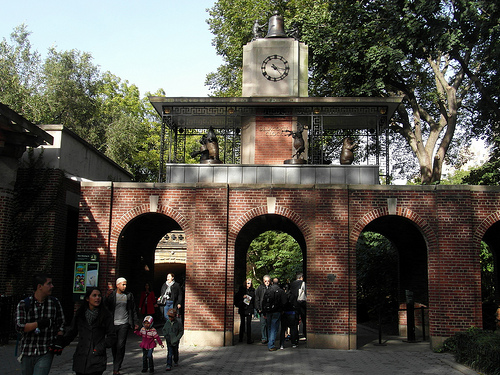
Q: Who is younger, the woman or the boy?
A: The boy is younger than the woman.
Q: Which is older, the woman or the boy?
A: The woman is older than the boy.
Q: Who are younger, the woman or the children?
A: The children are younger than the woman.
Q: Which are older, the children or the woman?
A: The woman are older than the children.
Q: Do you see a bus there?
A: No, there are no buses.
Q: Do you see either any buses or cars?
A: No, there are no buses or cars.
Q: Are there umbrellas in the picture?
A: No, there are no umbrellas.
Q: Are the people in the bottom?
A: Yes, the people are in the bottom of the image.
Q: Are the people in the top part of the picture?
A: No, the people are in the bottom of the image.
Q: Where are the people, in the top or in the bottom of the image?
A: The people are in the bottom of the image.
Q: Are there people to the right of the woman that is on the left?
A: Yes, there are people to the right of the woman.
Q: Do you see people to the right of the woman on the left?
A: Yes, there are people to the right of the woman.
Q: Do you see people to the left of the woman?
A: No, the people are to the right of the woman.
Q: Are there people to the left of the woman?
A: No, the people are to the right of the woman.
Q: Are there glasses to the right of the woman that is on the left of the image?
A: No, there are people to the right of the woman.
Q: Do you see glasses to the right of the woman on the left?
A: No, there are people to the right of the woman.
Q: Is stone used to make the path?
A: Yes, the path is made of stone.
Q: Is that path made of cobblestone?
A: No, the path is made of stone.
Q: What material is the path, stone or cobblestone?
A: The path is made of stone.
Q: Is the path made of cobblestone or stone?
A: The path is made of stone.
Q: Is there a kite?
A: No, there are no kites.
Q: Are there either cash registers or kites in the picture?
A: No, there are no kites or cash registers.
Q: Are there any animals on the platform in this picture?
A: Yes, there is an animal on the platform.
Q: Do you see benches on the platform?
A: No, there is an animal on the platform.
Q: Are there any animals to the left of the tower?
A: Yes, there is an animal to the left of the tower.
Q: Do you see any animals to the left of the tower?
A: Yes, there is an animal to the left of the tower.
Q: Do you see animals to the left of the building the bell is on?
A: Yes, there is an animal to the left of the tower.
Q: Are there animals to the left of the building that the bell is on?
A: Yes, there is an animal to the left of the tower.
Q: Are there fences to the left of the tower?
A: No, there is an animal to the left of the tower.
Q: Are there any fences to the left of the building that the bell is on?
A: No, there is an animal to the left of the tower.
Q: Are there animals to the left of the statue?
A: Yes, there is an animal to the left of the statue.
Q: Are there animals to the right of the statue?
A: No, the animal is to the left of the statue.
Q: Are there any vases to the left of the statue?
A: No, there is an animal to the left of the statue.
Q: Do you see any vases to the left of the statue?
A: No, there is an animal to the left of the statue.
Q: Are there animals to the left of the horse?
A: Yes, there is an animal to the left of the horse.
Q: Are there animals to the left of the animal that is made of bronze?
A: Yes, there is an animal to the left of the horse.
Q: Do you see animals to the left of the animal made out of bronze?
A: Yes, there is an animal to the left of the horse.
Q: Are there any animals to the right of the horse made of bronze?
A: No, the animal is to the left of the horse.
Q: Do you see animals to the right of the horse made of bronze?
A: No, the animal is to the left of the horse.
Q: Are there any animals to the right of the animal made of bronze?
A: No, the animal is to the left of the horse.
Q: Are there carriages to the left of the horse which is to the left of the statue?
A: No, there is an animal to the left of the horse.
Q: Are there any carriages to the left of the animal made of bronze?
A: No, there is an animal to the left of the horse.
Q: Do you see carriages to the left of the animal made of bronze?
A: No, there is an animal to the left of the horse.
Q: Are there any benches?
A: No, there are no benches.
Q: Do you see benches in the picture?
A: No, there are no benches.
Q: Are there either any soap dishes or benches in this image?
A: No, there are no benches or soap dishes.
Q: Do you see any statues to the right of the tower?
A: Yes, there is a statue to the right of the tower.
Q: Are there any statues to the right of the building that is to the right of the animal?
A: Yes, there is a statue to the right of the tower.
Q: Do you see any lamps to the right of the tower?
A: No, there is a statue to the right of the tower.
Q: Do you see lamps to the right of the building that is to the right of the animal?
A: No, there is a statue to the right of the tower.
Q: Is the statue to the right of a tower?
A: Yes, the statue is to the right of a tower.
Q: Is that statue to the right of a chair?
A: No, the statue is to the right of a tower.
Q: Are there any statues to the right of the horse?
A: Yes, there is a statue to the right of the horse.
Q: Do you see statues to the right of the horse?
A: Yes, there is a statue to the right of the horse.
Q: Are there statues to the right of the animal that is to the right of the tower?
A: Yes, there is a statue to the right of the horse.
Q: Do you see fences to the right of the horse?
A: No, there is a statue to the right of the horse.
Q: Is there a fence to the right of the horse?
A: No, there is a statue to the right of the horse.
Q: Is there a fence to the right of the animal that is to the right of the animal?
A: No, there is a statue to the right of the horse.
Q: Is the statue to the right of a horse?
A: Yes, the statue is to the right of a horse.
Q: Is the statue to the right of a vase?
A: No, the statue is to the right of a horse.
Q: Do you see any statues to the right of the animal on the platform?
A: Yes, there is a statue to the right of the animal.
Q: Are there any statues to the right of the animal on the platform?
A: Yes, there is a statue to the right of the animal.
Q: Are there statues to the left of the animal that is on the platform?
A: No, the statue is to the right of the animal.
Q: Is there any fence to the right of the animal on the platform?
A: No, there is a statue to the right of the animal.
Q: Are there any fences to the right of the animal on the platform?
A: No, there is a statue to the right of the animal.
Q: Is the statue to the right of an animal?
A: Yes, the statue is to the right of an animal.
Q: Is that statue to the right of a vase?
A: No, the statue is to the right of an animal.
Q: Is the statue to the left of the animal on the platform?
A: No, the statue is to the right of the animal.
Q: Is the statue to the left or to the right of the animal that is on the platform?
A: The statue is to the right of the animal.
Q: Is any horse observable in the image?
A: Yes, there is a horse.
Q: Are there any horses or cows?
A: Yes, there is a horse.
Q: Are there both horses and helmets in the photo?
A: No, there is a horse but no helmets.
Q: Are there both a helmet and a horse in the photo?
A: No, there is a horse but no helmets.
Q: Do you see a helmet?
A: No, there are no helmets.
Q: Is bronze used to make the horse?
A: Yes, the horse is made of bronze.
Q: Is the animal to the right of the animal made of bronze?
A: Yes, the horse is made of bronze.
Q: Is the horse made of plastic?
A: No, the horse is made of bronze.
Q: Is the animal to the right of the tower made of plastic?
A: No, the horse is made of bronze.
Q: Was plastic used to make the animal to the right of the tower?
A: No, the horse is made of bronze.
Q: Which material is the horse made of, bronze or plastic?
A: The horse is made of bronze.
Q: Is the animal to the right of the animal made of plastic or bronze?
A: The horse is made of bronze.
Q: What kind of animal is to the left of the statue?
A: The animal is a horse.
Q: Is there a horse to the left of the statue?
A: Yes, there is a horse to the left of the statue.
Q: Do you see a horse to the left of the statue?
A: Yes, there is a horse to the left of the statue.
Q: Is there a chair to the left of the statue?
A: No, there is a horse to the left of the statue.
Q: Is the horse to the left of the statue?
A: Yes, the horse is to the left of the statue.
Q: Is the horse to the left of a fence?
A: No, the horse is to the left of the statue.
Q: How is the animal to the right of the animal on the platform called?
A: The animal is a horse.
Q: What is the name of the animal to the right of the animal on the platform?
A: The animal is a horse.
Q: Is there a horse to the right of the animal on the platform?
A: Yes, there is a horse to the right of the animal.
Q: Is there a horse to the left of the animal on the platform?
A: No, the horse is to the right of the animal.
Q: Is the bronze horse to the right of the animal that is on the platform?
A: Yes, the horse is to the right of the animal.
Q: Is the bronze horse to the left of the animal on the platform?
A: No, the horse is to the right of the animal.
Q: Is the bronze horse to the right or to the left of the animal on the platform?
A: The horse is to the right of the animal.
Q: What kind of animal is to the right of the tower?
A: The animal is a horse.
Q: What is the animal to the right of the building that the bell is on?
A: The animal is a horse.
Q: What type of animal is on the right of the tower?
A: The animal is a horse.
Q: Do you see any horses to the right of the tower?
A: Yes, there is a horse to the right of the tower.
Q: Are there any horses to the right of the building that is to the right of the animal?
A: Yes, there is a horse to the right of the tower.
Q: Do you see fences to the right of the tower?
A: No, there is a horse to the right of the tower.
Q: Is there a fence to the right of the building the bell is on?
A: No, there is a horse to the right of the tower.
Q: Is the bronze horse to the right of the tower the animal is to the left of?
A: Yes, the horse is to the right of the tower.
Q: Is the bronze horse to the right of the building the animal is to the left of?
A: Yes, the horse is to the right of the tower.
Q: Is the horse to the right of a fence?
A: No, the horse is to the right of the tower.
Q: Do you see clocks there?
A: Yes, there is a clock.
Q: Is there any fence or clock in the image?
A: Yes, there is a clock.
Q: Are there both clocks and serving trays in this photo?
A: No, there is a clock but no serving trays.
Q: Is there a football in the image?
A: No, there are no footballs.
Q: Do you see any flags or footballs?
A: No, there are no footballs or flags.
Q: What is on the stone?
A: The clock is on the stone.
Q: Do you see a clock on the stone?
A: Yes, there is a clock on the stone.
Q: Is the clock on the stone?
A: Yes, the clock is on the stone.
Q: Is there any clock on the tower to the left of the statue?
A: Yes, there is a clock on the tower.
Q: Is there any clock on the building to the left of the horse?
A: Yes, there is a clock on the tower.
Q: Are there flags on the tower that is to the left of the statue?
A: No, there is a clock on the tower.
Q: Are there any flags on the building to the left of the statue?
A: No, there is a clock on the tower.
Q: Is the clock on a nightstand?
A: No, the clock is on the tower.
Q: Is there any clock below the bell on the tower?
A: Yes, there is a clock below the bell.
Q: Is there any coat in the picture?
A: Yes, there is a coat.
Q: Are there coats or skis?
A: Yes, there is a coat.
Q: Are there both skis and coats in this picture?
A: No, there is a coat but no skis.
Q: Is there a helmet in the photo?
A: No, there are no helmets.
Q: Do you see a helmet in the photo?
A: No, there are no helmets.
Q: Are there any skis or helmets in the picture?
A: No, there are no helmets or skis.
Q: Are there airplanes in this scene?
A: No, there are no airplanes.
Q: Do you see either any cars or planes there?
A: No, there are no planes or cars.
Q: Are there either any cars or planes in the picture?
A: No, there are no planes or cars.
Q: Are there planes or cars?
A: No, there are no planes or cars.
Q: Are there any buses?
A: No, there are no buses.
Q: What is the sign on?
A: The sign is on the building.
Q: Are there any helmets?
A: No, there are no helmets.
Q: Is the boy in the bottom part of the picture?
A: Yes, the boy is in the bottom of the image.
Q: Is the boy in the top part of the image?
A: No, the boy is in the bottom of the image.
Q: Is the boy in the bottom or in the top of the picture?
A: The boy is in the bottom of the image.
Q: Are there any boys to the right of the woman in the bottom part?
A: Yes, there is a boy to the right of the woman.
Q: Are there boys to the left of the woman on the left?
A: No, the boy is to the right of the woman.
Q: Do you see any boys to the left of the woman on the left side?
A: No, the boy is to the right of the woman.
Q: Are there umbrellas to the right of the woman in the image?
A: No, there is a boy to the right of the woman.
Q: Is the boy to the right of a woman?
A: Yes, the boy is to the right of a woman.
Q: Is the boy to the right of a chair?
A: No, the boy is to the right of a woman.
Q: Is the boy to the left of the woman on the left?
A: No, the boy is to the right of the woman.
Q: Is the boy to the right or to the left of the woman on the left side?
A: The boy is to the right of the woman.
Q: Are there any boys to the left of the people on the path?
A: Yes, there is a boy to the left of the people.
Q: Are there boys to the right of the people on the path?
A: No, the boy is to the left of the people.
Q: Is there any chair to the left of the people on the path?
A: No, there is a boy to the left of the people.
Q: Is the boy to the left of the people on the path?
A: Yes, the boy is to the left of the people.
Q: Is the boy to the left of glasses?
A: No, the boy is to the left of the people.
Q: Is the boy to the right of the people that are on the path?
A: No, the boy is to the left of the people.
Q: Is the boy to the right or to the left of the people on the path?
A: The boy is to the left of the people.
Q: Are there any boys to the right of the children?
A: Yes, there is a boy to the right of the children.